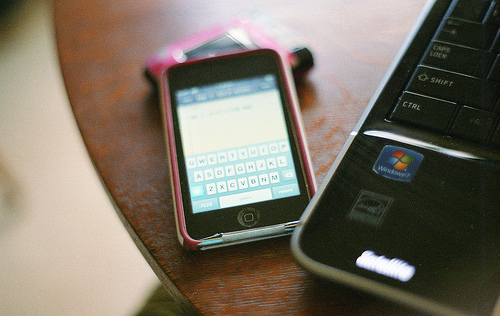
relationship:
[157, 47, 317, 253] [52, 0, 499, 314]
cellphone on desk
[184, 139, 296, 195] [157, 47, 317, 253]
keyboard on cellphone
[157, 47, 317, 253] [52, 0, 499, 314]
cellphone on table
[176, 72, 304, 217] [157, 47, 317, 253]
interface on cellphone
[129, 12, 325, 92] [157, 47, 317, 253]
flip phone behind cellphone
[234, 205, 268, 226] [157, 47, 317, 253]
button on cellphone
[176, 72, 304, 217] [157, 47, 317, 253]
screen of cellphone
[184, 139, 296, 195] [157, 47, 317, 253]
keyboard of cellphone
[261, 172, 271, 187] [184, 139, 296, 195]
letter on keyboard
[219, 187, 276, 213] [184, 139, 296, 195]
space bar on keyboard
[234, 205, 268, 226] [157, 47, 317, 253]
button of cellphone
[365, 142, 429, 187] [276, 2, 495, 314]
sticker on computer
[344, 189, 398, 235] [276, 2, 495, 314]
sticker on laptop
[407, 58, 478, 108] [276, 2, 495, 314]
key on laptop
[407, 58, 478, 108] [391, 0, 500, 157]
key on keyboard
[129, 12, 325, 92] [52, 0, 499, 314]
cellphone on table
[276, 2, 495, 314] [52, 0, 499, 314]
laptop on table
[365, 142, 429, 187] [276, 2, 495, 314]
symbol on laptop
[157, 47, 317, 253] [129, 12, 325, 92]
cellphone under phone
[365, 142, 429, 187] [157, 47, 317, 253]
sticker on cellphone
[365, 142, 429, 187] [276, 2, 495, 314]
sticker on phone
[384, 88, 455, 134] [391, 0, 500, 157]
button on keyboard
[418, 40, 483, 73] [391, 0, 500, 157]
button on keyboard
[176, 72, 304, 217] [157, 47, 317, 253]
screen on cellphone